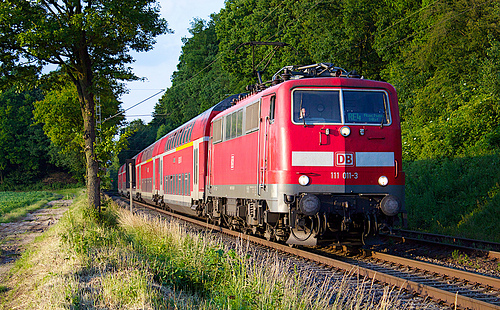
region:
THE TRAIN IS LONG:
[110, 61, 411, 261]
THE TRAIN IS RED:
[112, 60, 403, 270]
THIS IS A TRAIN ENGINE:
[197, 57, 412, 242]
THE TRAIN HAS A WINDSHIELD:
[285, 80, 395, 136]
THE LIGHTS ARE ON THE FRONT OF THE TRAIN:
[288, 122, 391, 200]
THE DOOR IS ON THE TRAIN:
[255, 98, 280, 189]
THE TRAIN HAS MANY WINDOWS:
[112, 97, 268, 207]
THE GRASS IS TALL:
[27, 175, 453, 308]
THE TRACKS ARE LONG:
[115, 173, 497, 308]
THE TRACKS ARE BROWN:
[114, 192, 499, 309]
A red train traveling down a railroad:
[117, 62, 402, 249]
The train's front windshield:
[290, 89, 389, 125]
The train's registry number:
[330, 170, 359, 180]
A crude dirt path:
[0, 197, 72, 276]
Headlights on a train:
[298, 194, 400, 216]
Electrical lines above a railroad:
[100, 0, 481, 120]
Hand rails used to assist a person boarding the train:
[253, 118, 272, 195]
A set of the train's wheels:
[210, 215, 286, 241]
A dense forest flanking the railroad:
[122, 0, 497, 146]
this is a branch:
[32, 87, 81, 142]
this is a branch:
[413, 132, 467, 204]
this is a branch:
[401, 25, 466, 93]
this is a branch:
[184, 37, 232, 91]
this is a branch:
[275, 2, 341, 53]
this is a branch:
[33, 101, 87, 161]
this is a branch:
[429, 100, 472, 174]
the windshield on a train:
[286, 69, 405, 141]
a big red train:
[189, 35, 407, 222]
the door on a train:
[235, 112, 296, 205]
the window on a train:
[213, 93, 285, 154]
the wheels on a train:
[211, 178, 362, 244]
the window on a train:
[291, 65, 411, 135]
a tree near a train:
[48, 105, 223, 244]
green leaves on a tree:
[290, 13, 362, 51]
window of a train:
[290, 84, 347, 126]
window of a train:
[345, 87, 399, 124]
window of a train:
[240, 95, 265, 127]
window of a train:
[223, 105, 250, 134]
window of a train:
[210, 119, 227, 141]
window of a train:
[182, 118, 196, 145]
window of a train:
[166, 130, 188, 142]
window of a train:
[146, 144, 157, 152]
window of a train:
[135, 172, 153, 197]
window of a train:
[165, 171, 195, 192]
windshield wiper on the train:
[295, 85, 316, 128]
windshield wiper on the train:
[378, 90, 389, 130]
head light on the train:
[298, 171, 308, 186]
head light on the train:
[378, 174, 390, 185]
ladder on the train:
[247, 112, 273, 203]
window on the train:
[216, 104, 250, 138]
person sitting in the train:
[296, 100, 311, 122]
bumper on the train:
[293, 188, 408, 218]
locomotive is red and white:
[203, 63, 420, 245]